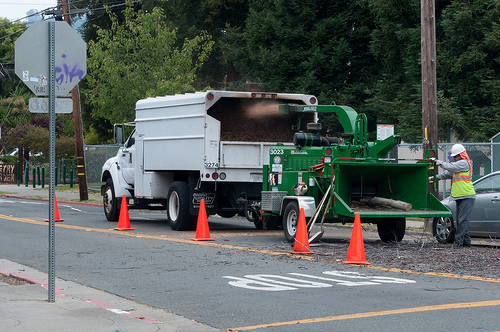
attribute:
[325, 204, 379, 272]
cone — orange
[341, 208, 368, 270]
cone — orange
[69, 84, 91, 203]
pole — leaning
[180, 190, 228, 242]
cone — orange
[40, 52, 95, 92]
graffitti — purple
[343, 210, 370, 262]
cone — orange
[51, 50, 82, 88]
graffiti — purple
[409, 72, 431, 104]
pole — light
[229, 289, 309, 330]
line — yellow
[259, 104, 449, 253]
wood chipper — green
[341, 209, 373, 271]
cone — orange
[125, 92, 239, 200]
truck — white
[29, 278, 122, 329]
concrete walkway — orange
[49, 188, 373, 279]
cones — orange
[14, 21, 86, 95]
sign — stop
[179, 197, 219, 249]
cone — orange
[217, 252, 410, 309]
white text — bold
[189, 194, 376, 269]
cones — orange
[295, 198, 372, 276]
cones — orange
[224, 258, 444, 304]
text — white, bold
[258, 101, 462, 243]
trailer — green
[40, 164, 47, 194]
post — green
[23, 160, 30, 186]
post — green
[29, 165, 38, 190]
post — green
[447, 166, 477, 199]
yellow — bright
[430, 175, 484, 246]
car — silver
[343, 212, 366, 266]
cone — orange